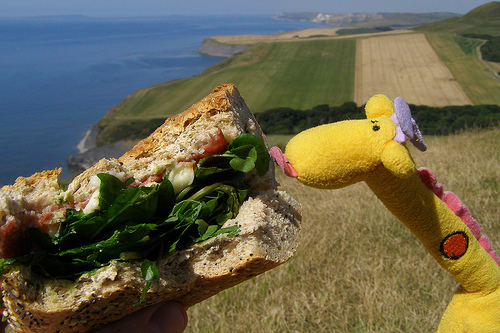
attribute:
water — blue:
[2, 5, 373, 206]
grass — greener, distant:
[293, 57, 320, 96]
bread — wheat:
[81, 104, 258, 302]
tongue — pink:
[267, 141, 298, 182]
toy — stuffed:
[259, 80, 499, 326]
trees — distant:
[253, 99, 499, 135]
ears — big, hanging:
[375, 147, 427, 180]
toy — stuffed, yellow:
[272, 88, 497, 330]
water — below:
[3, 3, 177, 77]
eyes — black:
[367, 116, 379, 131]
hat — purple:
[387, 86, 430, 153]